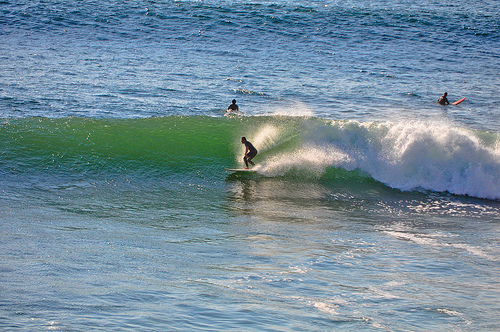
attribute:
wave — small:
[223, 85, 269, 96]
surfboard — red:
[226, 164, 260, 177]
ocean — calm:
[0, 0, 498, 328]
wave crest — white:
[318, 119, 464, 191]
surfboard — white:
[227, 162, 253, 177]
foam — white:
[272, 111, 445, 226]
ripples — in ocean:
[32, 198, 401, 330]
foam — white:
[309, 299, 338, 318]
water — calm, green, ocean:
[3, 4, 498, 328]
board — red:
[453, 94, 465, 105]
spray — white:
[238, 120, 360, 183]